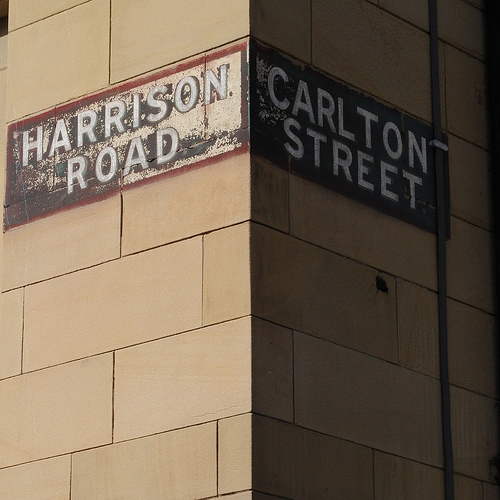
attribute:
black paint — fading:
[173, 112, 246, 167]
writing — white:
[266, 58, 448, 222]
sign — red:
[22, 47, 266, 194]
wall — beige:
[29, 202, 201, 414]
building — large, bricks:
[2, 2, 497, 498]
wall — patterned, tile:
[6, 4, 498, 497]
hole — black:
[373, 271, 391, 301]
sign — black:
[18, 61, 235, 159]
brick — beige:
[107, 308, 304, 462]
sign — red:
[5, 39, 252, 234]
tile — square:
[41, 257, 204, 322]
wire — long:
[420, 7, 458, 499]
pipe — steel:
[426, 3, 458, 497]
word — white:
[21, 57, 233, 197]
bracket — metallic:
[425, 135, 452, 153]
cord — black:
[427, 0, 456, 498]